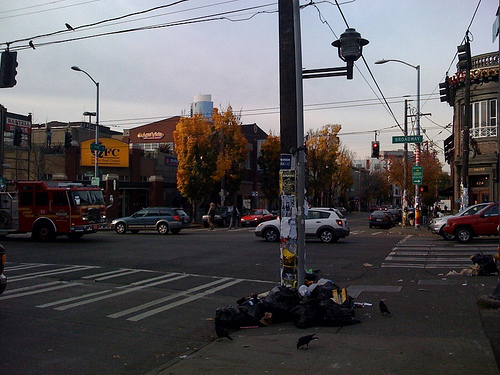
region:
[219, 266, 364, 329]
bags of garbage on the street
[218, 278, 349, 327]
black garbage on the street corer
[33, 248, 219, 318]
white lines on the road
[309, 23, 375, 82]
street light on a pole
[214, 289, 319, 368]
crows eating garbage off the street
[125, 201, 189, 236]
green SUV driving on the road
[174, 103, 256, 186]
tree with yellow leaves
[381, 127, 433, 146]
green street sign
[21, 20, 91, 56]
birds on a wire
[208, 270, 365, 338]
trash bags on sidewalk and street corner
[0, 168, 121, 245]
red fire truck in middle of intersection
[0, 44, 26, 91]
signal light above intersection and fire truck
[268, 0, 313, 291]
telephone pole on street corner next to trash bags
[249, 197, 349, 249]
white suv in middle of intersection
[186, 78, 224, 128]
blue and white water tower in the distance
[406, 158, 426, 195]
green and white sign on silver pole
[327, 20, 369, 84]
street lamp under telephone wires on corner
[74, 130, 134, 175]
orange sign on front of red brick building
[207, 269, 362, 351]
pile of trash next to post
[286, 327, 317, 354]
black crow eating trash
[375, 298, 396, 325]
black crow eating trash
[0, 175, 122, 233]
large red fire truck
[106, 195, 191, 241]
blue van on the street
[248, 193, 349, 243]
white van at the intersection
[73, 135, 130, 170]
yellow and red post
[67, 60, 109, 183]
tall silver light pole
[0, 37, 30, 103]
hanging black traffic light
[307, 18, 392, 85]
a light on top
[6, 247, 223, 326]
white lines in road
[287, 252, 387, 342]
a man sitting near pole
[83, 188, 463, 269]
a group of cars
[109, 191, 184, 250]
a car on road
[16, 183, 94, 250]
a big truck in road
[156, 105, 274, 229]
a large tree in road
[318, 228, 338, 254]
wheel of the car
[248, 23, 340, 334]
a electric pole in road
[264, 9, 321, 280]
a tall brown telephone pole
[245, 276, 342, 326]
a big bunch of garbage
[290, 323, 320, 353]
a bird eating something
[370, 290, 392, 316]
a bird walking around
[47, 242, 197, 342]
the lines of a crosswalk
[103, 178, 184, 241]
a minivan in the road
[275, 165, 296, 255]
a bunch of paper ads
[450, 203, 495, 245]
the front of a red car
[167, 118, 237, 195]
a bunch of brown leaves on a tree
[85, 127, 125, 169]
the yellow sign of a storefront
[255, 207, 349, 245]
White car behind a wooden pole.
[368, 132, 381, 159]
Red traffic light hanging over a street.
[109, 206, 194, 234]
Green station wagon driving by a fire truck.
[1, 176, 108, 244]
Red fire truck driving thru an intersection.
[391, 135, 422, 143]
Green and white street name sign.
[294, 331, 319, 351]
Closest black bird on the sidewalk.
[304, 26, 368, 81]
Black and glass street lamp.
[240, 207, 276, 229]
Red car with headlights on across the street.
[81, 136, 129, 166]
Yellow building sign across the street.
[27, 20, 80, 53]
Two back birds on a power line.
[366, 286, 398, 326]
Bird on the ground.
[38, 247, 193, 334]
White lines in the street.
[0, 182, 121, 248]
A red fire truck.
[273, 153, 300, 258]
Paper on the pole.